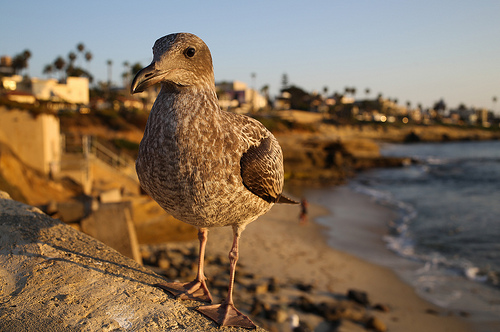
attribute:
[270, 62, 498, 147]
buildings — distance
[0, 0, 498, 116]
sky — blue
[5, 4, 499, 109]
sky — blue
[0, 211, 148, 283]
black shadow — thin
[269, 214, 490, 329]
sand — brown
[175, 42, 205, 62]
eye — small, black, beady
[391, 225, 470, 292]
wave — small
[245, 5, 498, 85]
sky — clear, blue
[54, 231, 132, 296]
shadow — legs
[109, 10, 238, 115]
bird — brown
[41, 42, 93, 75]
palm trees — green, large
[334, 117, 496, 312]
sea shore — ocean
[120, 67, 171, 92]
beak — long, brown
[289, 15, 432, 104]
clouds — white